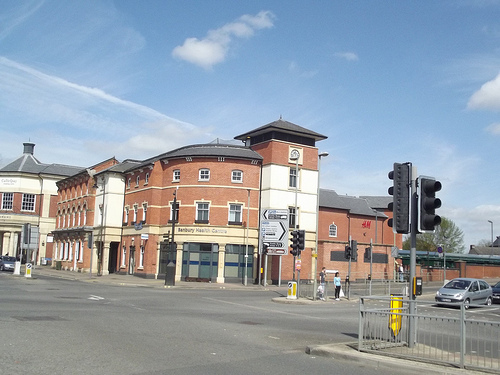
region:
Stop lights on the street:
[385, 157, 450, 235]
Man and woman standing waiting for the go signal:
[316, 257, 348, 304]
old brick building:
[4, 96, 495, 271]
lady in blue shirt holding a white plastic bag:
[330, 261, 345, 303]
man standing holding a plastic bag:
[314, 261, 329, 304]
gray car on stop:
[439, 265, 492, 315]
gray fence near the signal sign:
[356, 296, 498, 361]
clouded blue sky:
[56, 6, 472, 128]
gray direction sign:
[256, 212, 293, 267]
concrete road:
[21, 283, 273, 356]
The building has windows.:
[168, 163, 260, 220]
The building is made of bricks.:
[126, 133, 307, 282]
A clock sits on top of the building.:
[289, 137, 315, 174]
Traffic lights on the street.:
[379, 154, 440, 249]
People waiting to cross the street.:
[318, 256, 345, 308]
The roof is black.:
[147, 144, 265, 162]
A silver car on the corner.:
[433, 273, 491, 304]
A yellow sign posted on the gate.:
[381, 278, 413, 333]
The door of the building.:
[195, 253, 234, 292]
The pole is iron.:
[408, 251, 431, 343]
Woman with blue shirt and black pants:
[331, 267, 350, 301]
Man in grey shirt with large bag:
[313, 262, 329, 304]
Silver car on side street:
[431, 271, 498, 318]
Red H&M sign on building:
[356, 212, 378, 239]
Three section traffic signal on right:
[415, 167, 447, 243]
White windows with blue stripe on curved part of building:
[157, 238, 257, 283]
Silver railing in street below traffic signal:
[354, 290, 499, 373]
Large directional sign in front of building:
[253, 205, 294, 262]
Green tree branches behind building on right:
[400, 216, 470, 276]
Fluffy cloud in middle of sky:
[174, 10, 286, 72]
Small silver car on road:
[424, 276, 497, 312]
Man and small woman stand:
[310, 260, 350, 297]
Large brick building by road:
[131, 90, 341, 279]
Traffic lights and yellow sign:
[339, 151, 458, 338]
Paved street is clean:
[16, 281, 293, 368]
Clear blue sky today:
[47, 17, 440, 138]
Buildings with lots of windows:
[5, 185, 91, 251]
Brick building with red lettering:
[306, 206, 387, 233]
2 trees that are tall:
[393, 216, 490, 266]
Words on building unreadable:
[164, 228, 238, 240]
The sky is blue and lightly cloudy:
[1, 0, 499, 252]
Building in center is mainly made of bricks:
[55, 116, 397, 282]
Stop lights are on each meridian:
[284, 162, 442, 357]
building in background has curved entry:
[1, 137, 82, 266]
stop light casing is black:
[288, 163, 440, 265]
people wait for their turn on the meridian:
[311, 263, 346, 306]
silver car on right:
[432, 275, 495, 312]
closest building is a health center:
[151, 223, 258, 284]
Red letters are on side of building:
[359, 214, 372, 234]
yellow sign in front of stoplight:
[385, 293, 404, 346]